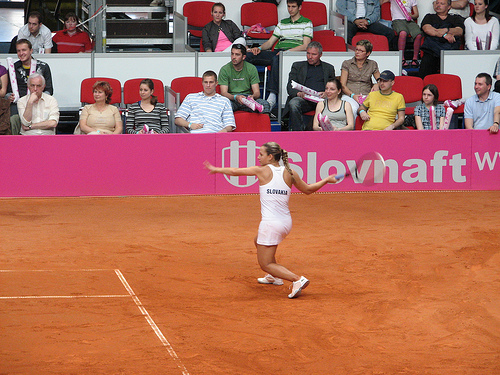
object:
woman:
[197, 136, 348, 305]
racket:
[333, 148, 390, 187]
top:
[253, 161, 293, 215]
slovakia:
[266, 186, 290, 195]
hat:
[371, 69, 398, 84]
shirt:
[356, 89, 409, 134]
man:
[13, 72, 63, 139]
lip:
[31, 90, 41, 96]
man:
[357, 69, 408, 131]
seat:
[232, 110, 272, 133]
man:
[459, 70, 500, 133]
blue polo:
[463, 90, 499, 131]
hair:
[252, 135, 297, 181]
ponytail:
[281, 146, 297, 181]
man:
[216, 40, 268, 117]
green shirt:
[217, 59, 262, 98]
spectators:
[124, 79, 170, 136]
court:
[0, 195, 497, 374]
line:
[108, 259, 189, 374]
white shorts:
[252, 215, 297, 251]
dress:
[252, 159, 296, 249]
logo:
[218, 138, 270, 191]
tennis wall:
[0, 134, 215, 194]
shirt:
[16, 93, 60, 135]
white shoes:
[286, 275, 311, 300]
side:
[257, 146, 269, 165]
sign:
[212, 130, 496, 194]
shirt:
[172, 92, 239, 133]